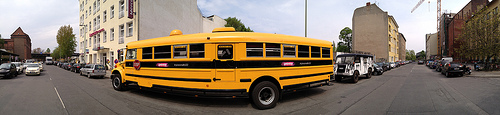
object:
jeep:
[331, 54, 377, 83]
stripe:
[51, 87, 65, 108]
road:
[361, 78, 459, 95]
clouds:
[22, 6, 62, 25]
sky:
[195, 0, 469, 19]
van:
[73, 64, 107, 79]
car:
[24, 67, 41, 76]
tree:
[222, 17, 249, 33]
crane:
[410, 0, 447, 30]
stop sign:
[128, 62, 142, 69]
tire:
[245, 81, 284, 110]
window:
[211, 44, 238, 59]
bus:
[117, 17, 336, 110]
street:
[0, 64, 134, 106]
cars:
[23, 63, 43, 69]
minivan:
[76, 64, 106, 79]